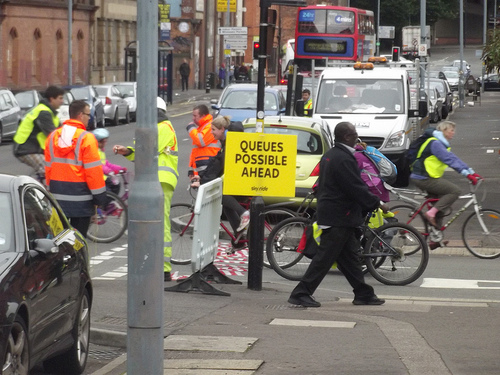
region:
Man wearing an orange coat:
[41, 97, 114, 240]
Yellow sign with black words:
[220, 130, 292, 196]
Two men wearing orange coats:
[40, 100, 222, 240]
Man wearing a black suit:
[285, 120, 380, 306]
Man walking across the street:
[285, 117, 381, 307]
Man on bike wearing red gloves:
[391, 115, 492, 256]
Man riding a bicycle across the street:
[405, 115, 495, 265]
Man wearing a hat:
[11, 82, 66, 183]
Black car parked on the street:
[1, 172, 101, 373]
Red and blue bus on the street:
[290, 3, 377, 73]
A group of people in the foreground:
[1, 76, 496, 286]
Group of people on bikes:
[72, 106, 497, 291]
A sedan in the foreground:
[1, 158, 108, 373]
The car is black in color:
[3, 165, 115, 372]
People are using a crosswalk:
[4, 80, 494, 300]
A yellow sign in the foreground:
[215, 123, 307, 203]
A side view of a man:
[289, 118, 389, 313]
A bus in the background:
[276, 2, 387, 91]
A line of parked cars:
[2, 68, 162, 150]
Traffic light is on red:
[246, 33, 263, 65]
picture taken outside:
[1, 1, 495, 358]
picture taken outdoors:
[3, 7, 478, 374]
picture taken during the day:
[15, 18, 499, 356]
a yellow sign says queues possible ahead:
[228, 133, 302, 193]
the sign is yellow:
[228, 134, 288, 195]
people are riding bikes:
[376, 144, 489, 242]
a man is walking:
[317, 140, 383, 328]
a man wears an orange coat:
[56, 129, 92, 201]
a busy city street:
[193, 55, 410, 267]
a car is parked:
[18, 188, 114, 361]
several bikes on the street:
[21, 70, 497, 299]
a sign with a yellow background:
[227, 132, 293, 196]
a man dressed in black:
[296, 149, 385, 309]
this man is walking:
[298, 123, 383, 313]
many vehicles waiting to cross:
[296, 39, 476, 149]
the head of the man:
[334, 121, 359, 148]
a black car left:
[1, 180, 93, 369]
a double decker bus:
[296, 4, 378, 77]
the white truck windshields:
[318, 76, 403, 115]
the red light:
[390, 47, 400, 63]